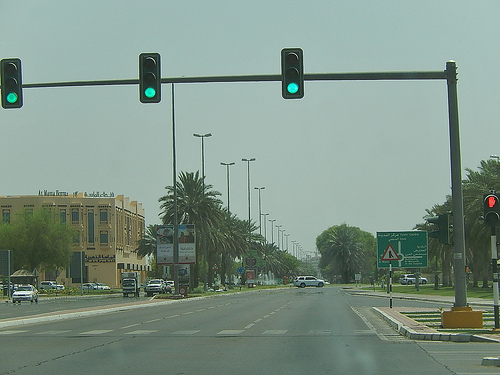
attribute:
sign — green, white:
[375, 231, 432, 271]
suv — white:
[291, 274, 331, 292]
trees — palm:
[318, 220, 379, 289]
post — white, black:
[438, 51, 486, 329]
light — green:
[7, 92, 17, 101]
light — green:
[145, 87, 154, 95]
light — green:
[286, 82, 297, 93]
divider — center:
[153, 280, 300, 300]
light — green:
[128, 39, 178, 121]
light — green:
[284, 78, 307, 96]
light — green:
[140, 84, 162, 106]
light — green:
[0, 91, 23, 108]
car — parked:
[13, 283, 38, 310]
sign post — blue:
[370, 227, 431, 272]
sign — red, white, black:
[378, 235, 405, 267]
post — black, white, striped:
[441, 59, 470, 305]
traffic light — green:
[280, 47, 308, 99]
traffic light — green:
[141, 53, 162, 100]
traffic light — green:
[1, 55, 22, 105]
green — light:
[282, 80, 297, 93]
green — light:
[142, 87, 154, 97]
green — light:
[7, 89, 17, 105]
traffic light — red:
[481, 191, 499, 235]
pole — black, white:
[487, 228, 499, 328]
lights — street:
[190, 128, 316, 269]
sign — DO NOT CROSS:
[477, 186, 497, 214]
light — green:
[274, 41, 311, 104]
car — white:
[288, 267, 329, 295]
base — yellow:
[434, 300, 484, 328]